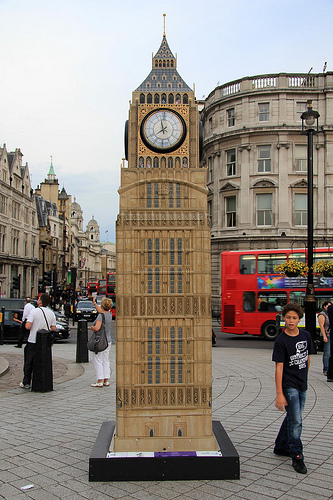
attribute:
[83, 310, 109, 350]
handbag — gray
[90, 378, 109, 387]
shoes — walking , women's  , comfortable  , White  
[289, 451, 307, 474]
shoes — black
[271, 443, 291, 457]
shoes — black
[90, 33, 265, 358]
statue — small, Big Ben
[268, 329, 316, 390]
shirt — white 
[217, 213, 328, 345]
double decker — red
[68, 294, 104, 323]
car — black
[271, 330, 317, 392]
t shirt —  tee,   black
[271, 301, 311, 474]
boy —  Older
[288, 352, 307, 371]
writing —  white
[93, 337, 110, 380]
pants — white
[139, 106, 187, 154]
face — white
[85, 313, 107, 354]
handbag —   black,  Oversized,  hobo style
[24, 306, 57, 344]
t shirt — white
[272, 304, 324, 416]
boy —  walking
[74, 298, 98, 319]
car —  Dark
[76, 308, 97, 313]
headlights —  illuminated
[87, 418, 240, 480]
base — black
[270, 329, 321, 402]
shirt — black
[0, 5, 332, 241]
sky — daytime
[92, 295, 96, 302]
hand — the right ,  woman's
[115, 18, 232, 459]
tower — clock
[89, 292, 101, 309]
hand — up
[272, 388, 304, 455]
jeans —  blue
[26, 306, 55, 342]
shirt —   white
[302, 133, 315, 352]
post —   black